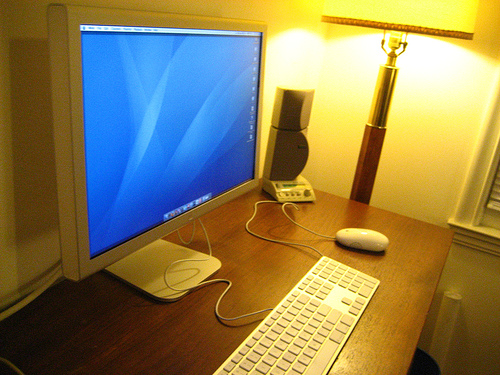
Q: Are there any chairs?
A: No, there are no chairs.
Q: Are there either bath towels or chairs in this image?
A: No, there are no chairs or bath towels.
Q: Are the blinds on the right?
A: Yes, the blinds are on the right of the image.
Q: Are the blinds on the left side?
A: No, the blinds are on the right of the image.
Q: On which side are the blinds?
A: The blinds are on the right of the image.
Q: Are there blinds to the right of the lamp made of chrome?
A: Yes, there are blinds to the right of the lamp.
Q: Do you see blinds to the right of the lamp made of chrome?
A: Yes, there are blinds to the right of the lamp.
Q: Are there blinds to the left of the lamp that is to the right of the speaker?
A: No, the blinds are to the right of the lamp.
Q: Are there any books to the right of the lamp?
A: No, there are blinds to the right of the lamp.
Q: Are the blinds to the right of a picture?
A: No, the blinds are to the right of a lamp.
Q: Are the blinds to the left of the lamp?
A: No, the blinds are to the right of the lamp.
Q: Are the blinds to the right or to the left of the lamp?
A: The blinds are to the right of the lamp.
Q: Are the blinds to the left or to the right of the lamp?
A: The blinds are to the right of the lamp.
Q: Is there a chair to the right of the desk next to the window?
A: No, there are blinds to the right of the desk.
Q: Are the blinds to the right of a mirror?
A: No, the blinds are to the right of the desk.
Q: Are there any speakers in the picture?
A: Yes, there is a speaker.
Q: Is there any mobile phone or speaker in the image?
A: Yes, there is a speaker.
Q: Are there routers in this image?
A: No, there are no routers.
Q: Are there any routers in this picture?
A: No, there are no routers.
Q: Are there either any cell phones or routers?
A: No, there are no routers or cell phones.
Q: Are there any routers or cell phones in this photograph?
A: No, there are no routers or cell phones.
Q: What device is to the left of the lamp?
A: The device is a speaker.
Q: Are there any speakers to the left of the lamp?
A: Yes, there is a speaker to the left of the lamp.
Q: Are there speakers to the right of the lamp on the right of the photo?
A: No, the speaker is to the left of the lamp.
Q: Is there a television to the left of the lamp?
A: No, there is a speaker to the left of the lamp.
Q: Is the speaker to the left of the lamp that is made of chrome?
A: Yes, the speaker is to the left of the lamp.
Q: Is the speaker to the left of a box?
A: No, the speaker is to the left of the lamp.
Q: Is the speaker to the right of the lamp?
A: No, the speaker is to the left of the lamp.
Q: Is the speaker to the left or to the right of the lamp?
A: The speaker is to the left of the lamp.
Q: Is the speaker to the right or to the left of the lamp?
A: The speaker is to the left of the lamp.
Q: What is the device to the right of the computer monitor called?
A: The device is a speaker.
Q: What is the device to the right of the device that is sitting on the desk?
A: The device is a speaker.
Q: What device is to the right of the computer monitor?
A: The device is a speaker.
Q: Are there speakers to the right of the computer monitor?
A: Yes, there is a speaker to the right of the computer monitor.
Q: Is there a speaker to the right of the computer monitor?
A: Yes, there is a speaker to the right of the computer monitor.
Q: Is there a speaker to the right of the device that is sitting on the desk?
A: Yes, there is a speaker to the right of the computer monitor.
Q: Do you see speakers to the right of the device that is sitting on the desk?
A: Yes, there is a speaker to the right of the computer monitor.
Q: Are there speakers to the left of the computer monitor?
A: No, the speaker is to the right of the computer monitor.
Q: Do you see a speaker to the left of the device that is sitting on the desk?
A: No, the speaker is to the right of the computer monitor.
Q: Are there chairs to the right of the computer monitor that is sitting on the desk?
A: No, there is a speaker to the right of the computer monitor.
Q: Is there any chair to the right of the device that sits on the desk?
A: No, there is a speaker to the right of the computer monitor.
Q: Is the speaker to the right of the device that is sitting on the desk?
A: Yes, the speaker is to the right of the computer monitor.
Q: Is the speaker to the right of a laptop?
A: No, the speaker is to the right of the computer monitor.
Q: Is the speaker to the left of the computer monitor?
A: No, the speaker is to the right of the computer monitor.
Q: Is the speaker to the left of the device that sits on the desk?
A: No, the speaker is to the right of the computer monitor.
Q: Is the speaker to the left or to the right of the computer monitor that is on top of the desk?
A: The speaker is to the right of the computer monitor.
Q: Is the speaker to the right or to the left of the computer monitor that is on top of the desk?
A: The speaker is to the right of the computer monitor.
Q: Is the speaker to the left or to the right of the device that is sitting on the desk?
A: The speaker is to the right of the computer monitor.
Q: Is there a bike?
A: No, there are no bikes.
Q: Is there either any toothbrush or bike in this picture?
A: No, there are no bikes or toothbrushes.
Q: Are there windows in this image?
A: Yes, there is a window.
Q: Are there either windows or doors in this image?
A: Yes, there is a window.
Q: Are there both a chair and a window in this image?
A: No, there is a window but no chairs.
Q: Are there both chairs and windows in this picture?
A: No, there is a window but no chairs.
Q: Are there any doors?
A: No, there are no doors.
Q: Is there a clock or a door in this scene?
A: No, there are no doors or clocks.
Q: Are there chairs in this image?
A: No, there are no chairs.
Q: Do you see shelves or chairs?
A: No, there are no chairs or shelves.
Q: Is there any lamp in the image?
A: Yes, there is a lamp.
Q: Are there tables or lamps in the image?
A: Yes, there is a lamp.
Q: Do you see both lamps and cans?
A: No, there is a lamp but no cans.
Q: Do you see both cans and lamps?
A: No, there is a lamp but no cans.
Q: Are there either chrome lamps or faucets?
A: Yes, there is a chrome lamp.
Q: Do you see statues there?
A: No, there are no statues.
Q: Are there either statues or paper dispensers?
A: No, there are no statues or paper dispensers.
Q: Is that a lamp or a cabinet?
A: That is a lamp.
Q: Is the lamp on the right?
A: Yes, the lamp is on the right of the image.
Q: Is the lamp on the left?
A: No, the lamp is on the right of the image.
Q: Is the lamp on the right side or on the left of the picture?
A: The lamp is on the right of the image.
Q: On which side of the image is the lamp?
A: The lamp is on the right of the image.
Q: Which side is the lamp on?
A: The lamp is on the right of the image.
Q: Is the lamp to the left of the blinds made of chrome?
A: Yes, the lamp is made of chrome.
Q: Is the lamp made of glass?
A: No, the lamp is made of chrome.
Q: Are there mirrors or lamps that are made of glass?
A: No, there is a lamp but it is made of chrome.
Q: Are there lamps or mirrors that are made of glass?
A: No, there is a lamp but it is made of chrome.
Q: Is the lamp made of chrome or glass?
A: The lamp is made of chrome.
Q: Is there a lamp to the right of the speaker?
A: Yes, there is a lamp to the right of the speaker.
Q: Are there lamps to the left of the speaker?
A: No, the lamp is to the right of the speaker.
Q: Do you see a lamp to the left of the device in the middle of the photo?
A: No, the lamp is to the right of the speaker.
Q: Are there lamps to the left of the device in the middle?
A: No, the lamp is to the right of the speaker.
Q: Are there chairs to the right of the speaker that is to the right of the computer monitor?
A: No, there is a lamp to the right of the speaker.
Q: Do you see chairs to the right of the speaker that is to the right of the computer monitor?
A: No, there is a lamp to the right of the speaker.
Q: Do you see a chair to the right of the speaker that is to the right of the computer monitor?
A: No, there is a lamp to the right of the speaker.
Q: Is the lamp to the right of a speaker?
A: Yes, the lamp is to the right of a speaker.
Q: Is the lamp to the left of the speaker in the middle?
A: No, the lamp is to the right of the speaker.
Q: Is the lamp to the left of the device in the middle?
A: No, the lamp is to the right of the speaker.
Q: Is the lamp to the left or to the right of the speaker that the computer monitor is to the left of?
A: The lamp is to the right of the speaker.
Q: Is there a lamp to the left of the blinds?
A: Yes, there is a lamp to the left of the blinds.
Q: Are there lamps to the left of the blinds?
A: Yes, there is a lamp to the left of the blinds.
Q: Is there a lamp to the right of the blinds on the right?
A: No, the lamp is to the left of the blinds.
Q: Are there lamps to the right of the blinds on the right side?
A: No, the lamp is to the left of the blinds.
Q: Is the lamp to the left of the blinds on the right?
A: Yes, the lamp is to the left of the blinds.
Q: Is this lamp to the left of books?
A: No, the lamp is to the left of the blinds.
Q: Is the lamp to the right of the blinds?
A: No, the lamp is to the left of the blinds.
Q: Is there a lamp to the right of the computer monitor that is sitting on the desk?
A: Yes, there is a lamp to the right of the computer monitor.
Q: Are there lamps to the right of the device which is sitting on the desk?
A: Yes, there is a lamp to the right of the computer monitor.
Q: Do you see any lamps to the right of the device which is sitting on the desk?
A: Yes, there is a lamp to the right of the computer monitor.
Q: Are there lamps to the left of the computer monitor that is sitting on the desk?
A: No, the lamp is to the right of the computer monitor.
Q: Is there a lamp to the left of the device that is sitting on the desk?
A: No, the lamp is to the right of the computer monitor.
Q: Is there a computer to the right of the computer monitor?
A: No, there is a lamp to the right of the computer monitor.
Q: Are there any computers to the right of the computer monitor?
A: No, there is a lamp to the right of the computer monitor.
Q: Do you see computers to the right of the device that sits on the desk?
A: No, there is a lamp to the right of the computer monitor.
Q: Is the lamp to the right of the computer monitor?
A: Yes, the lamp is to the right of the computer monitor.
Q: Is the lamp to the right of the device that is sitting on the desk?
A: Yes, the lamp is to the right of the computer monitor.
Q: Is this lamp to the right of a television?
A: No, the lamp is to the right of the computer monitor.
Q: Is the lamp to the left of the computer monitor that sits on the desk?
A: No, the lamp is to the right of the computer monitor.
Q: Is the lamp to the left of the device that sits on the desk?
A: No, the lamp is to the right of the computer monitor.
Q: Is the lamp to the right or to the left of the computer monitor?
A: The lamp is to the right of the computer monitor.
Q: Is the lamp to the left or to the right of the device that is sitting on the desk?
A: The lamp is to the right of the computer monitor.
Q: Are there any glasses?
A: No, there are no glasses.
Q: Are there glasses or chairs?
A: No, there are no glasses or chairs.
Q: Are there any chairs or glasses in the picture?
A: No, there are no glasses or chairs.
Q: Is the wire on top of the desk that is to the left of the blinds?
A: Yes, the wire is on top of the desk.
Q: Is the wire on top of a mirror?
A: No, the wire is on top of the desk.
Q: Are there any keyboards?
A: Yes, there is a keyboard.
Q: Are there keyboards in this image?
A: Yes, there is a keyboard.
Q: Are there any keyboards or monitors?
A: Yes, there is a keyboard.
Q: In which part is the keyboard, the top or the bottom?
A: The keyboard is in the bottom of the image.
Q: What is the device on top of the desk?
A: The device is a keyboard.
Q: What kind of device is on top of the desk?
A: The device is a keyboard.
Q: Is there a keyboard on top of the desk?
A: Yes, there is a keyboard on top of the desk.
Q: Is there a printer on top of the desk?
A: No, there is a keyboard on top of the desk.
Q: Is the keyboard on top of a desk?
A: Yes, the keyboard is on top of a desk.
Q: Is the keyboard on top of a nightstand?
A: No, the keyboard is on top of a desk.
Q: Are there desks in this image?
A: Yes, there is a desk.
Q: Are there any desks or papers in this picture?
A: Yes, there is a desk.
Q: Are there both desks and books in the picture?
A: No, there is a desk but no books.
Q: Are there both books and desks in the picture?
A: No, there is a desk but no books.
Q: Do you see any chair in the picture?
A: No, there are no chairs.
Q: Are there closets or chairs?
A: No, there are no chairs or closets.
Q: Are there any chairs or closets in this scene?
A: No, there are no chairs or closets.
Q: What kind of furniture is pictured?
A: The furniture is a desk.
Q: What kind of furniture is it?
A: The piece of furniture is a desk.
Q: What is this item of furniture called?
A: This is a desk.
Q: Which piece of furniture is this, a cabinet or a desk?
A: This is a desk.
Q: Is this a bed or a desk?
A: This is a desk.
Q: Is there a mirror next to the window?
A: No, there is a desk next to the window.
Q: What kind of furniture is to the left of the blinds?
A: The piece of furniture is a desk.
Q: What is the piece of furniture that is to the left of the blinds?
A: The piece of furniture is a desk.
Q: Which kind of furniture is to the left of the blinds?
A: The piece of furniture is a desk.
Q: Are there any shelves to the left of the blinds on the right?
A: No, there is a desk to the left of the blinds.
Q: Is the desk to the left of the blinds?
A: Yes, the desk is to the left of the blinds.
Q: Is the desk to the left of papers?
A: No, the desk is to the left of the blinds.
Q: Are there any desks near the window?
A: Yes, there is a desk near the window.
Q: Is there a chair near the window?
A: No, there is a desk near the window.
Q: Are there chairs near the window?
A: No, there is a desk near the window.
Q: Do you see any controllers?
A: No, there are no controllers.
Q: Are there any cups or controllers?
A: No, there are no controllers or cups.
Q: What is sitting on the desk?
A: The computer monitor is sitting on the desk.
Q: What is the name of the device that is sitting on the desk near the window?
A: The device is a computer monitor.